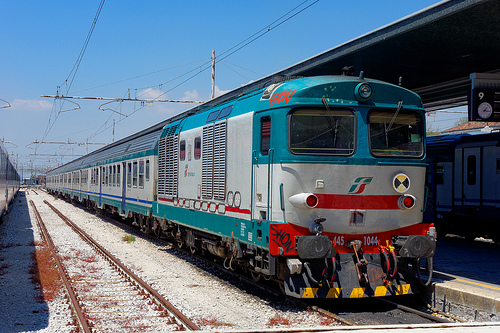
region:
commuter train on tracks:
[82, 65, 444, 300]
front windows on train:
[282, 98, 429, 173]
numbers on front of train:
[325, 228, 386, 254]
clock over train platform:
[465, 98, 495, 132]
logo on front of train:
[334, 172, 382, 203]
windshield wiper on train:
[315, 95, 345, 140]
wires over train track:
[34, 34, 249, 134]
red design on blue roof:
[258, 78, 315, 114]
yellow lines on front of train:
[294, 279, 425, 312]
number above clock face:
[471, 86, 489, 106]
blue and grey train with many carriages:
[41, 66, 437, 305]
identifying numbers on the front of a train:
[331, 229, 381, 251]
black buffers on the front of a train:
[295, 228, 438, 263]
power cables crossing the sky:
[23, 42, 253, 174]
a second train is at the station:
[419, 130, 497, 245]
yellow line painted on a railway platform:
[428, 270, 496, 297]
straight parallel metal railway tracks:
[24, 182, 200, 332]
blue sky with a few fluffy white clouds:
[2, 40, 354, 177]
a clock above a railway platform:
[475, 99, 497, 119]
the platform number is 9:
[469, 88, 493, 104]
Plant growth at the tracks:
[24, 245, 73, 311]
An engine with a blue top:
[153, 66, 443, 158]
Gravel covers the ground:
[71, 213, 227, 312]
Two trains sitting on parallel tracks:
[264, 74, 499, 301]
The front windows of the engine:
[274, 99, 440, 161]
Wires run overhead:
[24, 38, 229, 141]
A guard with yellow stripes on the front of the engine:
[276, 234, 437, 311]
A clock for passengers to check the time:
[467, 95, 496, 119]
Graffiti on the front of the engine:
[265, 216, 307, 259]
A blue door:
[112, 157, 145, 220]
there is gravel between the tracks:
[153, 251, 209, 296]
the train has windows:
[124, 157, 151, 190]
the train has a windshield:
[289, 102, 424, 162]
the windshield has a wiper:
[380, 97, 410, 153]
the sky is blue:
[8, 7, 73, 82]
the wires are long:
[30, 5, 119, 141]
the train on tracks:
[36, 73, 443, 291]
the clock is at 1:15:
[471, 97, 498, 121]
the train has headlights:
[293, 187, 425, 214]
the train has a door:
[251, 110, 272, 230]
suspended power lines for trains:
[51, 7, 186, 154]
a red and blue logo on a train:
[329, 158, 410, 210]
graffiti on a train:
[249, 209, 305, 262]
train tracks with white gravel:
[28, 199, 87, 234]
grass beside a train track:
[23, 235, 72, 307]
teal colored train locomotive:
[153, 87, 410, 261]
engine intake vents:
[196, 118, 246, 215]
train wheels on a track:
[151, 220, 207, 257]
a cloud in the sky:
[11, 81, 58, 119]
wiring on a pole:
[183, 36, 254, 88]